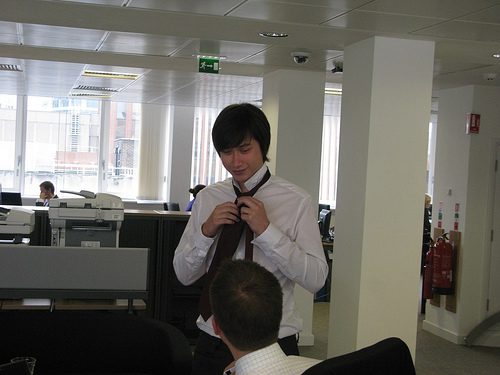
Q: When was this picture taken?
A: Daytime.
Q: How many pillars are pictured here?
A: 5.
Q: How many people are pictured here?
A: 4.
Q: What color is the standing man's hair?
A: Black.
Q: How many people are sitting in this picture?
A: 3.